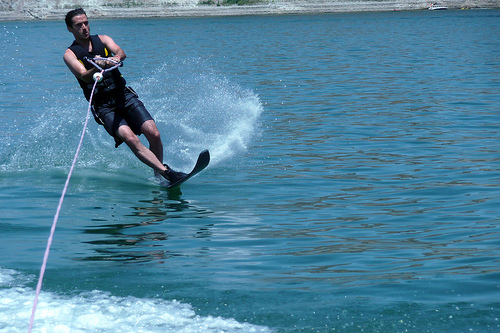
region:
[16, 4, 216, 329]
a water skier being pulled by a boat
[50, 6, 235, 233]
a man on a single water ski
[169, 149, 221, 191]
the tip of a water ski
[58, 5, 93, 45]
the head of a man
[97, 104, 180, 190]
the legs of a man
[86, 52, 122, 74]
the hands of a man gripped around the handle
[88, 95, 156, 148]
a black bathing suit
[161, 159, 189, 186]
the foot of the skier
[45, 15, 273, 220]
a guy going water skiing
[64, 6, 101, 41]
the head of an adult male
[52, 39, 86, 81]
the arm of an adult male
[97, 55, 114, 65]
the hands of an adult male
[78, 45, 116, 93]
the torso of an adult male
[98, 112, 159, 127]
the thighs of an adult male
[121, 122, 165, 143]
the knees of an adult male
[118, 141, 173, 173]
the shins of an adult male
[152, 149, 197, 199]
the feet of an adult male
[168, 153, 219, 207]
the water skis of an adult male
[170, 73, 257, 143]
a splash of water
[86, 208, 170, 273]
reflection in the water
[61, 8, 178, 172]
man is jet skiing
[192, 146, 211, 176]
a ski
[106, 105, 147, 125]
black shorts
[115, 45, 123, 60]
the mans arm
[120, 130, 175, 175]
legs of the man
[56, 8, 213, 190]
Person skiing on the water.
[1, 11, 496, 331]
Blue water covering the surface.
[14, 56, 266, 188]
Splashes of water in the air.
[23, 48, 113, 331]
rope in the man's hands.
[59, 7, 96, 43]
Dark hair on the man.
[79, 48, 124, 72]
Handle on the rope.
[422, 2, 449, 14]
boat in the water.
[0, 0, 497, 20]
Brick retaining wall in the background.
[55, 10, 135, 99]
black vest on the man.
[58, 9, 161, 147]
Black shorts on the man.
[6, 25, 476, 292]
water with skier in it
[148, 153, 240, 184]
skis on the person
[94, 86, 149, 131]
shorts on the man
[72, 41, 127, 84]
top on the man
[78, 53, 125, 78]
handle for ski rope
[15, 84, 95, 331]
rope connecting man to boat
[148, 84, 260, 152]
splash of water made by skis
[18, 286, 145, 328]
white water coming from boat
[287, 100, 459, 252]
blue water skier is in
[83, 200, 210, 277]
reflection of the skier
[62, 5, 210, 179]
man on water skiis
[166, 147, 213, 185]
long thin black skiis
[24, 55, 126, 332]
long thin purple line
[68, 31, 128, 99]
small black cloth vest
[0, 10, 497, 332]
large open body of water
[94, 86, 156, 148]
wet black beach shorts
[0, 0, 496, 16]
large long wide grey shore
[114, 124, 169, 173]
long white thin leg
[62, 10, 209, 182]
man on a ski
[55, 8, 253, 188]
the man is skiing in the water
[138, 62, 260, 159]
the water is splashing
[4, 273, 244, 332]
white bubbles on the water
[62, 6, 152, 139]
the man is dressed in black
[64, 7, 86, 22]
the hair is black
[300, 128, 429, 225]
the water has waves